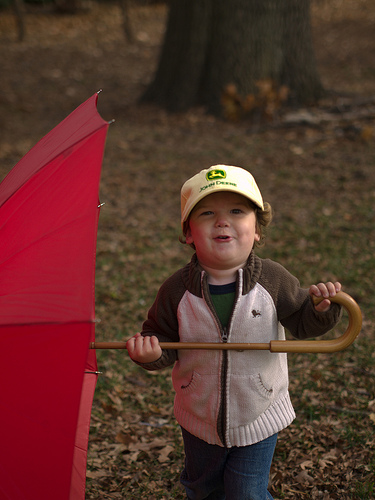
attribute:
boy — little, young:
[121, 161, 345, 499]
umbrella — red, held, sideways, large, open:
[1, 90, 365, 500]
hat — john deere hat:
[176, 162, 264, 239]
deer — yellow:
[205, 169, 228, 181]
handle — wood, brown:
[89, 284, 363, 357]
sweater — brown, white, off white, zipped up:
[132, 247, 344, 450]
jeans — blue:
[178, 417, 281, 499]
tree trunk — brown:
[136, 2, 350, 127]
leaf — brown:
[135, 436, 167, 450]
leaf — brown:
[291, 456, 317, 474]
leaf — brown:
[155, 443, 174, 465]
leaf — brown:
[105, 390, 125, 415]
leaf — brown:
[315, 451, 338, 470]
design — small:
[247, 306, 261, 321]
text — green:
[197, 180, 238, 194]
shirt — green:
[208, 279, 240, 333]